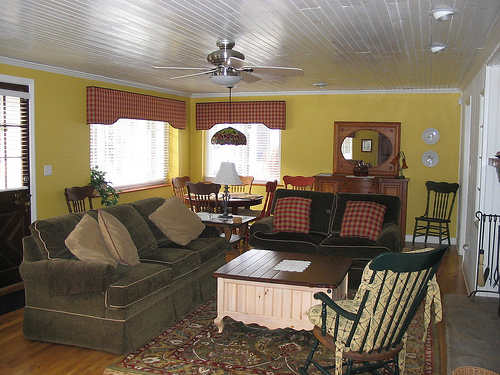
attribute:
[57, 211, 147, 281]
pillows — tan, throw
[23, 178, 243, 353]
couch — one